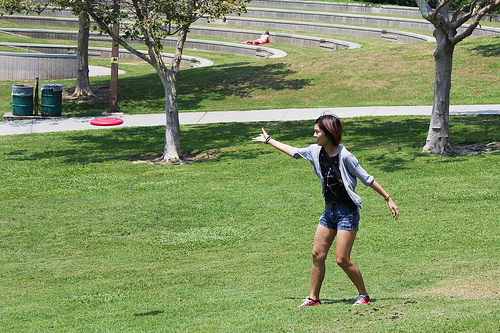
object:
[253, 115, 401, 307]
woman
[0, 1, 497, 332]
park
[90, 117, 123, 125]
frisbee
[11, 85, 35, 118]
garbage-can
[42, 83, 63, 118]
garbage-can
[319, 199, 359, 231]
shorts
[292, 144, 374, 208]
cardigan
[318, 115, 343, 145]
hair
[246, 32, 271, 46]
person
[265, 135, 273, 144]
bracelet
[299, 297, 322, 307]
shoe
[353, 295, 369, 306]
shoe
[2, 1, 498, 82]
amphitheater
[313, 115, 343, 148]
head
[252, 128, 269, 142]
hand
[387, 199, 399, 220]
hand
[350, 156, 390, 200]
arm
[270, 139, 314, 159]
arm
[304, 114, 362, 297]
body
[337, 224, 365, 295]
leg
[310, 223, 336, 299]
leg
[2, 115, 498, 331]
grass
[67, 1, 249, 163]
tree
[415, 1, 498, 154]
tree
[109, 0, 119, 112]
pole